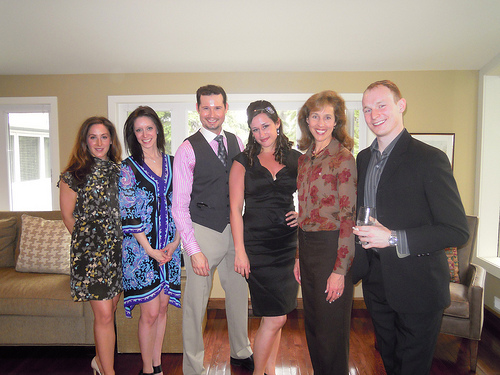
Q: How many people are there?
A: Six.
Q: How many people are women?
A: Four.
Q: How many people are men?
A: Two.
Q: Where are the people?
A: Living room.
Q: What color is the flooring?
A: Brown.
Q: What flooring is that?
A: Wooden.